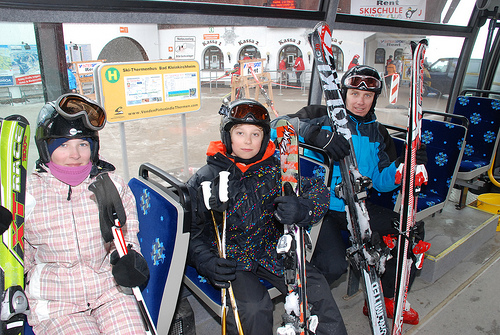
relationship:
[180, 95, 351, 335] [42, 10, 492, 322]
man on bus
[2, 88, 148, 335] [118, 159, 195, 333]
girl on seat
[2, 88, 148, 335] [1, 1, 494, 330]
girl riding bus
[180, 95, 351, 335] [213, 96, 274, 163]
man has a helmet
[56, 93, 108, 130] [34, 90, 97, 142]
goggles are falling off of helmet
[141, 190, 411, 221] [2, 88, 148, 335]
bus seat under girl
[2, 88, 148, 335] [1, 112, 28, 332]
girl holding green skis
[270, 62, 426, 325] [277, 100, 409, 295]
man wearing ski gear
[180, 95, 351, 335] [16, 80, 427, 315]
man on a ski lift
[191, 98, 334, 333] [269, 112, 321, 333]
boy holding skies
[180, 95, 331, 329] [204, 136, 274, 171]
man has hood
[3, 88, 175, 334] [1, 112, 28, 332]
girl holding green skis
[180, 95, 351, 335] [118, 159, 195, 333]
man on seat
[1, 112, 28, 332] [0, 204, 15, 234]
green skis in hand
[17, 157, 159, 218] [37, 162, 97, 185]
pink scarf around neck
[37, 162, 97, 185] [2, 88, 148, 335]
neck of girl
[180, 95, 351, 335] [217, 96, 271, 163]
man wearing helmet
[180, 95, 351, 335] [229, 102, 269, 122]
man wearing goggles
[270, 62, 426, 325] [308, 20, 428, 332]
man holding skiis